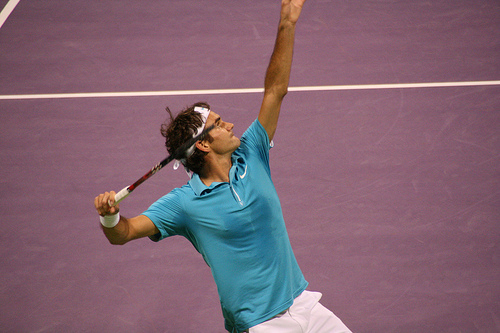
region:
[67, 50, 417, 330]
Man about to serve a tennis ball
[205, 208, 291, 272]
Sweat on the front of his shirt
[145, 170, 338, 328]
Blue polo shirt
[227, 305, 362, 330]
White dress shorts with pockets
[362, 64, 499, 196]
White line on the court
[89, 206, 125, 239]
White wristband on wrist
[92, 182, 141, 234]
Man has a clenched hand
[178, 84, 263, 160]
He is concentrating on the ball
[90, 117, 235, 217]
Tennis racket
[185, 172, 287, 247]
Blue shirt with white accents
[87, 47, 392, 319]
the player in tennis court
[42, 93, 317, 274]
player holding a racket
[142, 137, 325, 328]
the shirt is wet with sweat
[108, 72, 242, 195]
the headband is white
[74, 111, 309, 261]
the racket handle is white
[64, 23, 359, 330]
the player is looking up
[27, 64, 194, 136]
the line is white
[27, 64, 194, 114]
a line painted on the ground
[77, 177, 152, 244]
the wrist band is white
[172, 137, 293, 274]
the logo is nike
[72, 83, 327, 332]
man in a blue polo shirt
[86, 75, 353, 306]
man holding a tennis racket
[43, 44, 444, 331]
man wearing a sports headband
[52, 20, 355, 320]
man playing tennis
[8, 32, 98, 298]
part of a purple tennis court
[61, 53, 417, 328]
man with brown hair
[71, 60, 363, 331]
tennis player wearing white shorts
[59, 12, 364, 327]
tennis player in a blue shirt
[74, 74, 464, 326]
tennis player holding a racket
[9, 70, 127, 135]
white stripe on a tennis court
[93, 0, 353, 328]
man swinging tennis racquet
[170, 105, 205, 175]
white headband on man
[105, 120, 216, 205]
black, red and white tennis racquet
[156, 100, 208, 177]
short dark brown hair on man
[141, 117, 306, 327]
sweaty blue green polo shirt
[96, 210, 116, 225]
white wristband on man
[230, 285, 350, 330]
white shorts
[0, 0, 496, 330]
large tennis court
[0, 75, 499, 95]
white painted line on court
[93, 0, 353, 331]
man playing on tennis court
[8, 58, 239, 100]
a white line on the court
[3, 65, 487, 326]
a purple tennis court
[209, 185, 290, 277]
sweat stains on cloth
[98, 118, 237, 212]
a white handled tennis racket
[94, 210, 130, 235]
a soft white wristband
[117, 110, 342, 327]
a light blue polo shirt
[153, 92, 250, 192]
a man with white wristband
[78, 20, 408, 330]
a young man playing tennis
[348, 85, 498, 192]
scuff marks on court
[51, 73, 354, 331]
a young man in athletic clothing